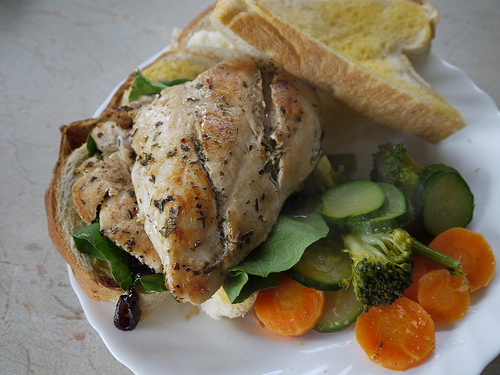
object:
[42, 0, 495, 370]
food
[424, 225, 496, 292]
carrot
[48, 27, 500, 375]
plate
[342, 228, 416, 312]
broccoli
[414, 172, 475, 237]
cucumber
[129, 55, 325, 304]
breast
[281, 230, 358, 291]
zucchini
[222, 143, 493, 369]
vegetable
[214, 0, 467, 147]
toast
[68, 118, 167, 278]
chicken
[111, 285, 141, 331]
cranberry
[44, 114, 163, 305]
bread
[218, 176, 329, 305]
lettuce